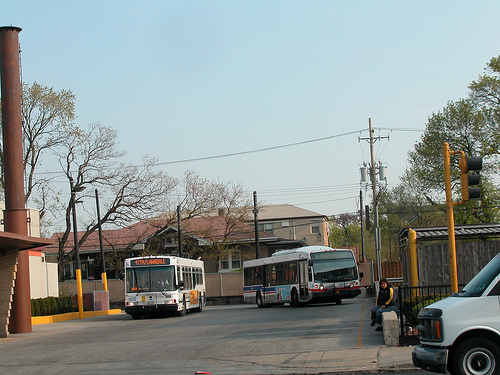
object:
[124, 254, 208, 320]
bus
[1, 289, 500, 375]
road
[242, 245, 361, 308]
bus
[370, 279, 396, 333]
woman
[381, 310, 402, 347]
barrier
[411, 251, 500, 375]
van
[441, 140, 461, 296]
pole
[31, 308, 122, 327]
curb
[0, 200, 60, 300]
building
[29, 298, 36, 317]
hedges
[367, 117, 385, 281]
pole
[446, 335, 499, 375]
tire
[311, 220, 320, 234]
window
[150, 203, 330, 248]
building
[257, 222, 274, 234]
window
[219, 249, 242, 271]
window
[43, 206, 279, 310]
building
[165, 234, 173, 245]
window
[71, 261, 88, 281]
window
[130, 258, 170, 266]
sign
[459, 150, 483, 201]
stoplight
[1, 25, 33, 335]
stack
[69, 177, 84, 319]
pole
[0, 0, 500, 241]
sky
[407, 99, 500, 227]
tree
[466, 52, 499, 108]
tree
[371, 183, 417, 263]
tree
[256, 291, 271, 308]
back-wheel